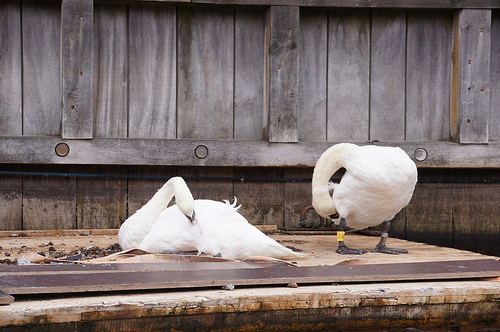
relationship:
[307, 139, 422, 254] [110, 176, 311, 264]
swan next to swan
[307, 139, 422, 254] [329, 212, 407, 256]
swan has legs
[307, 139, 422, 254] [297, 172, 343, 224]
swan has head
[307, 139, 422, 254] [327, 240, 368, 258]
swan has foot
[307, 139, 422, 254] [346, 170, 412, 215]
swan has breast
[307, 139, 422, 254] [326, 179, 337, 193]
swan has tail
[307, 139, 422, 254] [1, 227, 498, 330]
swan on stand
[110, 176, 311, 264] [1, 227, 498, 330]
swan on stand